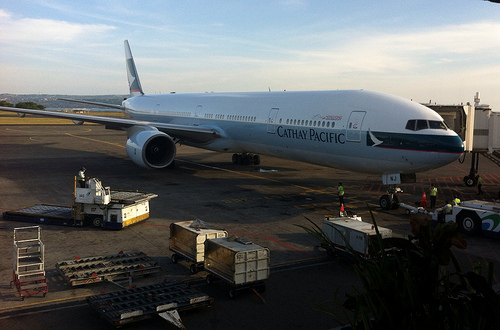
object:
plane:
[0, 35, 467, 215]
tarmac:
[30, 128, 224, 193]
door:
[343, 109, 366, 142]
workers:
[335, 182, 347, 208]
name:
[272, 125, 347, 144]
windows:
[330, 120, 336, 128]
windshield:
[427, 119, 444, 130]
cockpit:
[395, 101, 458, 141]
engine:
[122, 126, 176, 170]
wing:
[2, 102, 212, 136]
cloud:
[1, 17, 115, 42]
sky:
[138, 10, 313, 58]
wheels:
[379, 192, 402, 212]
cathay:
[276, 125, 308, 140]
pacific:
[309, 127, 347, 146]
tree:
[14, 99, 46, 111]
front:
[404, 98, 468, 165]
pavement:
[175, 180, 241, 221]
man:
[75, 166, 88, 190]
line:
[83, 135, 107, 145]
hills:
[0, 90, 51, 107]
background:
[12, 46, 106, 103]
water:
[47, 108, 61, 112]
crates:
[173, 220, 267, 285]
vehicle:
[74, 176, 158, 229]